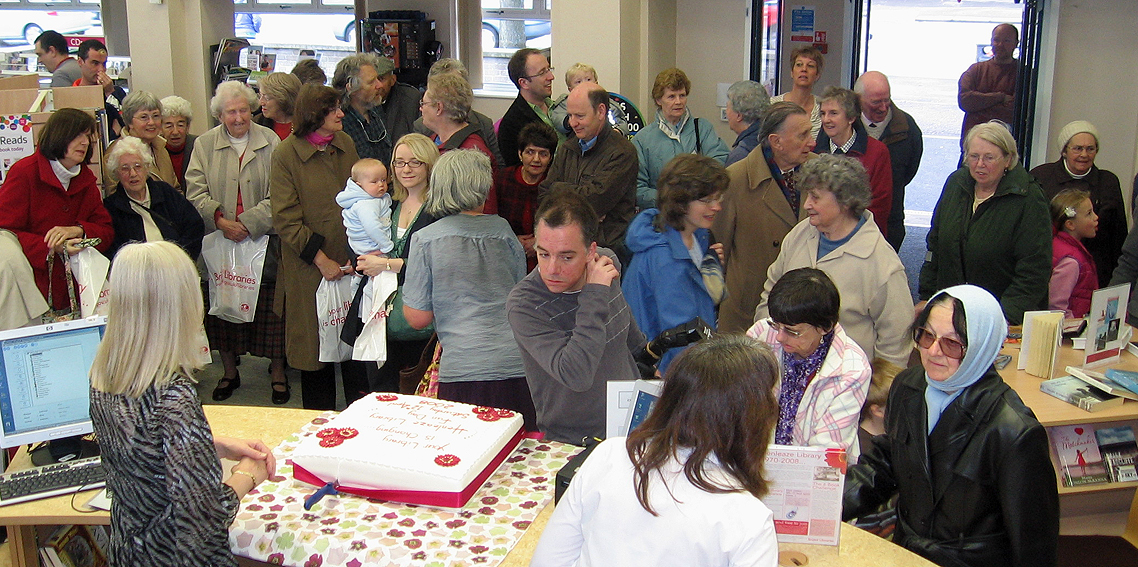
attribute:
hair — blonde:
[90, 239, 216, 400]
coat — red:
[1, 154, 112, 294]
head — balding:
[558, 79, 609, 143]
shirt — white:
[529, 435, 781, 565]